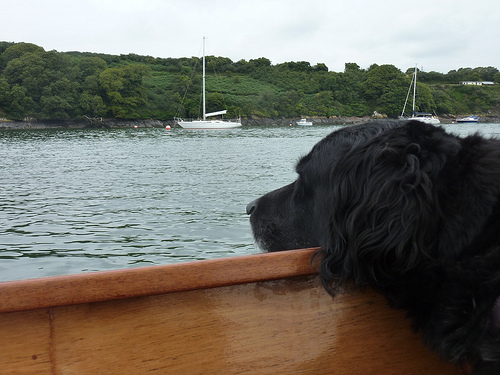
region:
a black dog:
[238, 92, 493, 359]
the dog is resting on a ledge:
[244, 111, 494, 362]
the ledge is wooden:
[8, 236, 428, 371]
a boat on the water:
[167, 25, 244, 129]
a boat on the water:
[381, 57, 450, 137]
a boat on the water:
[288, 115, 313, 127]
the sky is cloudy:
[247, 15, 455, 52]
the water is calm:
[47, 147, 196, 221]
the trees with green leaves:
[22, 41, 176, 117]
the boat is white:
[174, 86, 244, 137]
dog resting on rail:
[246, 163, 498, 363]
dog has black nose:
[245, 197, 269, 215]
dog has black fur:
[322, 124, 497, 331]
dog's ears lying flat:
[336, 116, 427, 228]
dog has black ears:
[330, 110, 486, 283]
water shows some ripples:
[10, 124, 223, 271]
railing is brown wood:
[23, 289, 424, 373]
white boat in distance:
[156, 56, 226, 136]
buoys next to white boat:
[133, 113, 173, 139]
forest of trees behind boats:
[28, 44, 498, 134]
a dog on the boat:
[178, 73, 497, 320]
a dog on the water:
[194, 84, 497, 334]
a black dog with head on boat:
[189, 70, 497, 344]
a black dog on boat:
[189, 79, 495, 349]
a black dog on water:
[204, 121, 486, 311]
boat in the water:
[134, 11, 276, 195]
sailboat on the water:
[171, 12, 304, 174]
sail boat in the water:
[150, 28, 287, 148]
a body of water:
[18, 155, 148, 220]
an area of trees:
[37, 37, 175, 112]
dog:
[222, 107, 487, 336]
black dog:
[254, 121, 474, 351]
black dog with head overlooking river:
[237, 121, 485, 321]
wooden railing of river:
[3, 263, 298, 374]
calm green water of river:
[23, 133, 242, 248]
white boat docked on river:
[178, 113, 248, 133]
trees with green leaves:
[14, 62, 164, 110]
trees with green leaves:
[222, 67, 392, 98]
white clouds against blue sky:
[33, 11, 348, 49]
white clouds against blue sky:
[292, 6, 474, 51]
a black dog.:
[245, 118, 497, 371]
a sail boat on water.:
[175, 35, 245, 135]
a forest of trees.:
[0, 32, 497, 124]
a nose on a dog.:
[239, 180, 271, 260]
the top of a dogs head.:
[278, 106, 424, 183]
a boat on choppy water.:
[175, 26, 243, 136]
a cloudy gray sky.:
[0, 1, 497, 74]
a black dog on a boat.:
[243, 117, 497, 374]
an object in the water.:
[160, 119, 177, 131]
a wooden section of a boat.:
[4, 248, 498, 374]